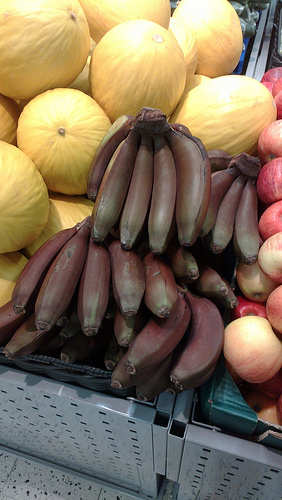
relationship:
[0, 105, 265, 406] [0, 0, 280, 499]
bananas at fruit stand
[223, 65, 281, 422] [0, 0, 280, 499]
apples at fruit stand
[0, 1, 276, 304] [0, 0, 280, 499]
melons at fruit stand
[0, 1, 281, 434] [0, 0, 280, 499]
fruit at fruit stand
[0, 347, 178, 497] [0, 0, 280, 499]
basket at fruit stand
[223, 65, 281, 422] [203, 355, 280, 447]
apples inside box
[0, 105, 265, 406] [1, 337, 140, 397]
bananas inside basket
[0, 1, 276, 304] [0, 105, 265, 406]
melons behind bananas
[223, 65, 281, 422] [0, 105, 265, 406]
apples beside bananas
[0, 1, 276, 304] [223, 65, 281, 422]
melons beside apples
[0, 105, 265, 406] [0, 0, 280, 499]
bananas on fruit stand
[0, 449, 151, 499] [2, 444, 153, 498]
tile on floor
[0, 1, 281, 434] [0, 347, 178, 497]
fruit sits on basket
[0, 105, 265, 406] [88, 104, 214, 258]
bananas are in bunch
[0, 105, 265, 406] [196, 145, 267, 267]
bananas are in bunch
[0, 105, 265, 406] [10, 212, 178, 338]
bananas are in bunch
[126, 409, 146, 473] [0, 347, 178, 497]
holes in basket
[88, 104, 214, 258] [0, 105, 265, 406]
bunch of bananas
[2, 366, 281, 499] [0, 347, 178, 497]
side of basket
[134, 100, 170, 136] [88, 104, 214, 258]
stem of bunch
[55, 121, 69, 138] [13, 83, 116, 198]
stem of squash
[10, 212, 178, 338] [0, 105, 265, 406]
bunch of bananas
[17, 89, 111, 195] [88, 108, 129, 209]
melon ext to banana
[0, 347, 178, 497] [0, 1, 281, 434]
basket hold fruit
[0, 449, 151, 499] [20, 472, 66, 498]
tile has black spots